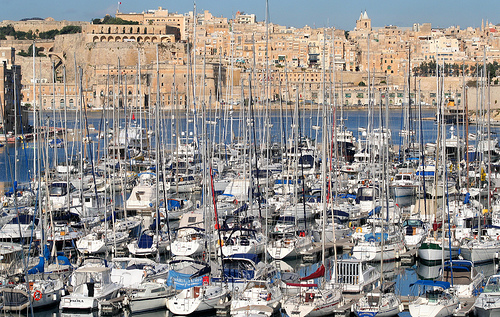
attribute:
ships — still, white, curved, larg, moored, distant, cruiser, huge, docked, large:
[123, 190, 248, 251]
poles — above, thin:
[183, 96, 250, 136]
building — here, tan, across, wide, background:
[85, 14, 161, 54]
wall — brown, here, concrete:
[235, 23, 311, 60]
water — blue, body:
[15, 159, 28, 167]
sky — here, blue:
[325, 8, 337, 12]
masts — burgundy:
[188, 276, 206, 284]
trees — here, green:
[101, 12, 132, 22]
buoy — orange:
[121, 111, 136, 139]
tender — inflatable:
[103, 283, 127, 297]